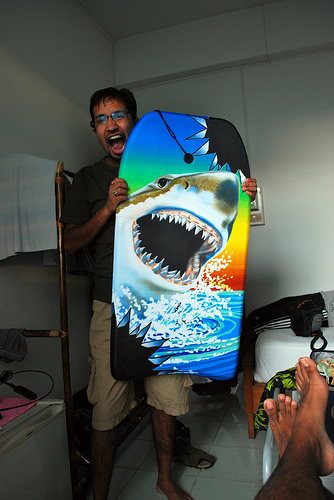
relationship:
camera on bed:
[282, 287, 326, 349] [214, 272, 326, 443]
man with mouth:
[45, 54, 210, 273] [97, 123, 147, 166]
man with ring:
[45, 54, 210, 273] [114, 185, 131, 202]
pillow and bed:
[279, 347, 324, 397] [214, 272, 326, 443]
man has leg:
[45, 54, 210, 273] [87, 396, 212, 499]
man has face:
[45, 54, 210, 273] [82, 107, 140, 159]